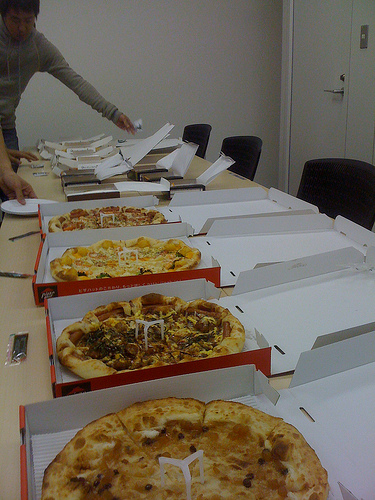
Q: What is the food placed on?
A: A large table.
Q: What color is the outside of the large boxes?
A: Red.